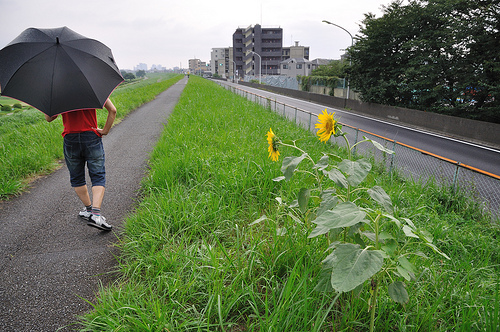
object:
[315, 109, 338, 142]
sunflower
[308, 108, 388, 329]
plant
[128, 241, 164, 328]
grass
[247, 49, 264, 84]
street light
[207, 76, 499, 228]
road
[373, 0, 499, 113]
trees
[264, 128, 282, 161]
sunflower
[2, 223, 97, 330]
asphalt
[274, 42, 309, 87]
buildings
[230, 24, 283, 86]
building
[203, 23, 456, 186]
right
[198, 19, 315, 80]
group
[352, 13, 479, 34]
top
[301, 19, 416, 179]
side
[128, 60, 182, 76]
skyline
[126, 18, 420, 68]
horizon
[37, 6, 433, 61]
sky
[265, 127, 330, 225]
plant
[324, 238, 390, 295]
leaves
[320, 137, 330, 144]
petals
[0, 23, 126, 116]
umbrella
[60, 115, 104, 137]
shirt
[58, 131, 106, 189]
jean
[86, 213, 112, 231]
shoes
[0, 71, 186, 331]
path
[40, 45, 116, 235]
man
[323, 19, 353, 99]
lamp post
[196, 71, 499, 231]
fence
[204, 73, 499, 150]
guard